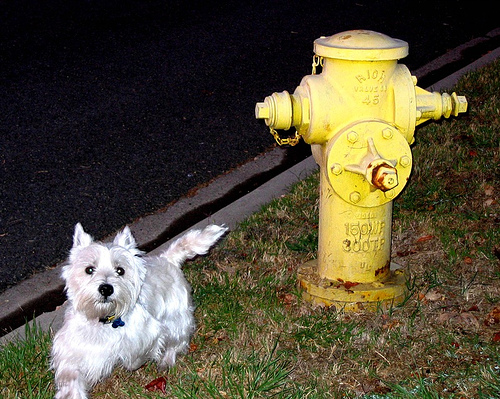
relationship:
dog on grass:
[48, 221, 229, 398] [0, 54, 499, 397]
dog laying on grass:
[48, 221, 229, 398] [0, 54, 499, 397]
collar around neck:
[97, 313, 117, 326] [70, 305, 138, 327]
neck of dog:
[70, 305, 138, 327] [48, 221, 229, 398]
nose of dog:
[99, 284, 115, 297] [48, 221, 229, 398]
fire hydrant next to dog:
[255, 29, 467, 315] [48, 221, 229, 398]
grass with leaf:
[0, 54, 499, 397] [146, 377, 167, 393]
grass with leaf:
[0, 54, 499, 397] [425, 290, 444, 303]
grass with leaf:
[0, 54, 499, 397] [490, 306, 500, 325]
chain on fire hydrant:
[269, 128, 302, 146] [255, 29, 467, 315]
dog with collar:
[48, 221, 229, 398] [97, 313, 117, 326]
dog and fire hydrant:
[48, 221, 229, 398] [255, 29, 467, 315]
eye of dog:
[86, 266, 94, 274] [48, 221, 229, 398]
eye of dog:
[116, 267, 126, 277] [48, 221, 229, 398]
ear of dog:
[71, 223, 92, 248] [48, 221, 229, 398]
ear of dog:
[116, 225, 138, 253] [48, 221, 229, 398]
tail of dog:
[161, 225, 229, 268] [48, 221, 229, 398]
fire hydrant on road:
[255, 29, 467, 315] [0, 0, 499, 341]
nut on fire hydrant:
[372, 166, 399, 193] [255, 29, 467, 315]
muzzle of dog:
[83, 274, 125, 319] [48, 221, 229, 398]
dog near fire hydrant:
[48, 221, 229, 398] [255, 29, 467, 315]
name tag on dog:
[111, 315, 125, 328] [48, 221, 229, 398]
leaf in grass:
[146, 377, 167, 393] [0, 54, 499, 397]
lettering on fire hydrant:
[343, 221, 387, 255] [255, 29, 467, 315]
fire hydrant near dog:
[255, 29, 467, 315] [48, 221, 229, 398]